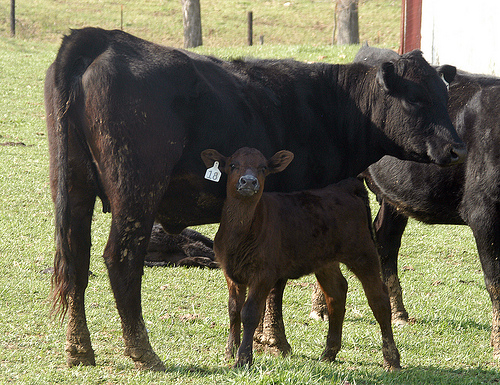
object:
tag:
[204, 161, 223, 182]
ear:
[201, 147, 227, 179]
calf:
[200, 142, 401, 376]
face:
[380, 47, 469, 167]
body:
[364, 61, 490, 356]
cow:
[46, 21, 470, 371]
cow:
[342, 37, 500, 365]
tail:
[52, 21, 73, 334]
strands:
[61, 205, 74, 326]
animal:
[145, 221, 219, 266]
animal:
[43, 22, 465, 373]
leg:
[101, 170, 176, 372]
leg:
[41, 78, 92, 365]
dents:
[115, 247, 130, 262]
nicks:
[113, 210, 148, 271]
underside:
[366, 153, 466, 232]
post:
[247, 10, 254, 49]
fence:
[5, 2, 420, 49]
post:
[9, 0, 16, 39]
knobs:
[125, 216, 139, 232]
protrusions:
[125, 103, 188, 216]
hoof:
[122, 348, 166, 373]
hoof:
[64, 343, 97, 372]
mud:
[122, 341, 163, 362]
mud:
[64, 331, 94, 355]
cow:
[146, 219, 220, 268]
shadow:
[353, 358, 497, 384]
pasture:
[0, 0, 494, 373]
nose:
[238, 176, 257, 188]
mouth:
[237, 185, 257, 194]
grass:
[5, 0, 500, 379]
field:
[7, 3, 493, 378]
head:
[199, 143, 293, 204]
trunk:
[335, 0, 361, 48]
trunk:
[182, 2, 202, 49]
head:
[371, 46, 466, 169]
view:
[0, 0, 494, 375]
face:
[225, 145, 270, 196]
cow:
[201, 131, 411, 373]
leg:
[233, 280, 270, 370]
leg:
[227, 276, 248, 360]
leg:
[317, 260, 350, 364]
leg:
[346, 254, 404, 369]